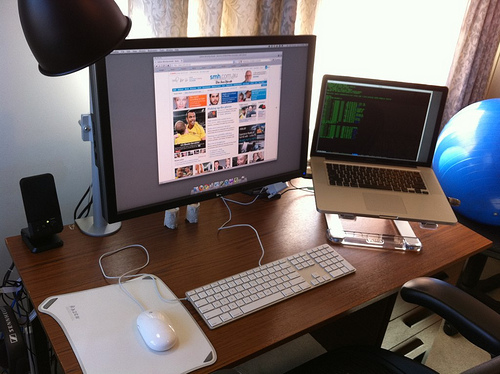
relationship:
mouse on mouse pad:
[134, 309, 176, 350] [53, 278, 209, 373]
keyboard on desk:
[187, 245, 354, 328] [6, 169, 492, 373]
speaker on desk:
[20, 174, 62, 251] [6, 169, 492, 373]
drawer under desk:
[368, 286, 443, 364] [6, 169, 492, 373]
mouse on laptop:
[361, 190, 407, 212] [316, 86, 461, 223]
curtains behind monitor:
[126, 1, 314, 45] [96, 39, 301, 209]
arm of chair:
[405, 278, 493, 336] [285, 286, 497, 373]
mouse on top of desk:
[134, 309, 176, 350] [6, 169, 492, 373]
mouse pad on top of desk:
[53, 278, 209, 373] [6, 169, 492, 373]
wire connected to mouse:
[102, 241, 186, 307] [134, 309, 176, 350]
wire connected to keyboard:
[215, 199, 277, 264] [187, 245, 354, 328]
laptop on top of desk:
[316, 86, 461, 223] [6, 169, 492, 373]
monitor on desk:
[96, 39, 301, 209] [6, 169, 492, 373]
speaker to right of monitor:
[20, 174, 62, 251] [96, 39, 301, 209]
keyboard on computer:
[187, 245, 354, 328] [96, 39, 301, 209]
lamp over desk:
[18, 2, 137, 77] [6, 169, 492, 373]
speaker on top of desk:
[20, 174, 62, 251] [6, 169, 492, 373]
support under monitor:
[165, 203, 206, 226] [96, 39, 301, 209]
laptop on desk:
[316, 86, 461, 223] [6, 169, 492, 373]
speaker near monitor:
[20, 174, 62, 251] [96, 39, 301, 209]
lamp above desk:
[18, 2, 137, 77] [6, 169, 492, 373]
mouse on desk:
[134, 309, 176, 350] [6, 169, 492, 373]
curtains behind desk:
[126, 1, 314, 45] [6, 169, 492, 373]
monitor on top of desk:
[96, 39, 301, 209] [6, 169, 492, 373]